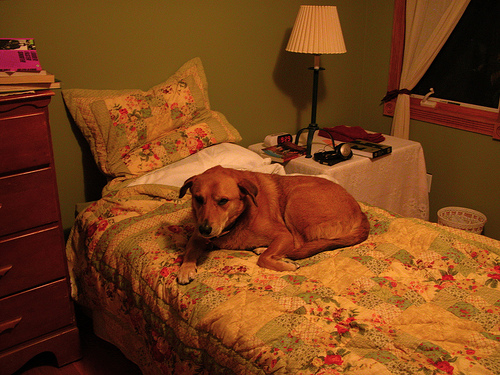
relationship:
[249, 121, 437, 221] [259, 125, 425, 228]
bedside with table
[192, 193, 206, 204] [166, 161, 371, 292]
eye of dog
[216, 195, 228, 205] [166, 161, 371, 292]
eye of dog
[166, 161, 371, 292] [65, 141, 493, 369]
dog on bed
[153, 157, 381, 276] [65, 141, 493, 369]
dog on top of bed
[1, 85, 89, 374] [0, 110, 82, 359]
chest of drawers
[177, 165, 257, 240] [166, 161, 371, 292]
head of dog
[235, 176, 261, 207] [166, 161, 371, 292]
ear of dog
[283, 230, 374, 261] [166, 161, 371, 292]
tail of dog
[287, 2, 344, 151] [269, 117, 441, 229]
lamp on table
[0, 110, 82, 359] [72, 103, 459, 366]
drawers next to bed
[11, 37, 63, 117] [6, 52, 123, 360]
books on dresser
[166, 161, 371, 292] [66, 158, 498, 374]
dog on bed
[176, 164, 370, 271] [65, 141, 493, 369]
dog on bed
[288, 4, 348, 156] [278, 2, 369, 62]
lamp with shade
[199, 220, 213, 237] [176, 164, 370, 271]
nose of dog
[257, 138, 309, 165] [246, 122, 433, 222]
book on table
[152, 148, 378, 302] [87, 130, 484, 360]
dog on bed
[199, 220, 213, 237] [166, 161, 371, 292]
nose on dog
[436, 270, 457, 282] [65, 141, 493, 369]
flower on bed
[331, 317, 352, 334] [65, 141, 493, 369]
flower on bed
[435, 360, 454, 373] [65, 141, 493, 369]
flower on bed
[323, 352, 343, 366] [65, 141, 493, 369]
flower on bed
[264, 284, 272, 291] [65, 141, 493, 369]
flower on bed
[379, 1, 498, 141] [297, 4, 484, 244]
window on wall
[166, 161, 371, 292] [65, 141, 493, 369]
dog laying on bed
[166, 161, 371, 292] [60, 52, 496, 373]
dog on bed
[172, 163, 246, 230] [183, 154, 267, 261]
head on dog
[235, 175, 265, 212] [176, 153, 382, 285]
ear of dog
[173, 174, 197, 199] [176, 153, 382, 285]
ear of dog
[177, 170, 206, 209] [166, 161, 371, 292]
ear of dog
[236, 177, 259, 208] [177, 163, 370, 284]
ear of dog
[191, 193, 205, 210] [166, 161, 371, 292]
eye of dog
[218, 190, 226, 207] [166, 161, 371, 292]
eye of dog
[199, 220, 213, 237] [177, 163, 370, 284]
nose of dog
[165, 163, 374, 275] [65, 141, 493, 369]
dog on bed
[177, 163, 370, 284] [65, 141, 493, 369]
dog on bed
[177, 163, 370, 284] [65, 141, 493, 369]
dog laying on bed